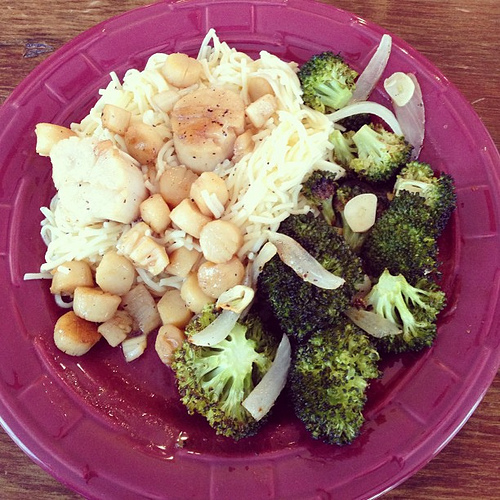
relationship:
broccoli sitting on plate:
[171, 307, 278, 442] [1, 1, 500, 500]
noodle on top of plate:
[43, 232, 109, 272] [1, 1, 500, 500]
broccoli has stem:
[348, 123, 415, 183] [350, 124, 377, 151]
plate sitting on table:
[1, 1, 500, 500] [1, 1, 500, 497]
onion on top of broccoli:
[251, 230, 346, 290] [254, 213, 364, 343]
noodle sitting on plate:
[240, 57, 248, 106] [1, 1, 500, 500]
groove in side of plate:
[10, 369, 46, 399] [1, 1, 500, 500]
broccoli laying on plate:
[171, 307, 278, 442] [1, 1, 500, 500]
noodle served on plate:
[43, 232, 109, 272] [1, 1, 500, 500]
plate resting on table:
[1, 1, 500, 500] [1, 1, 500, 497]